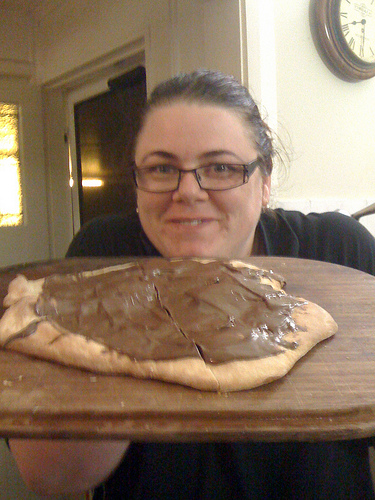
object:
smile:
[154, 210, 224, 235]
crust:
[0, 254, 337, 392]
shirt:
[63, 206, 375, 269]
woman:
[2, 70, 372, 498]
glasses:
[129, 154, 265, 194]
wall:
[279, 0, 373, 135]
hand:
[346, 18, 366, 26]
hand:
[360, 25, 366, 50]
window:
[0, 100, 29, 230]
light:
[0, 157, 17, 214]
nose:
[171, 169, 211, 204]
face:
[135, 102, 265, 254]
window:
[66, 98, 136, 190]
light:
[68, 177, 104, 188]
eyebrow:
[193, 148, 246, 160]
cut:
[160, 296, 222, 390]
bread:
[3, 248, 340, 394]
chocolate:
[40, 257, 299, 361]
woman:
[132, 73, 269, 267]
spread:
[39, 255, 299, 355]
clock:
[308, 0, 374, 81]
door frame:
[43, 31, 148, 254]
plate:
[2, 252, 375, 432]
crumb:
[87, 374, 100, 384]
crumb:
[118, 398, 126, 407]